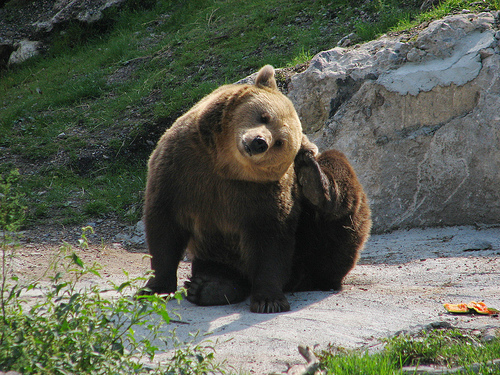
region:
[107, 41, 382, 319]
bear sitting on ground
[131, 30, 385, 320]
the bear is a grizzly bear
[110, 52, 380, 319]
bear is scratching its ear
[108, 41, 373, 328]
the bear is brown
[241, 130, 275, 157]
bear's nose is black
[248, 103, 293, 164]
bear's eyes are black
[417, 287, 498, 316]
orange object on ground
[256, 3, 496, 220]
concrete wall behind bear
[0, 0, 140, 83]
rocks in the grass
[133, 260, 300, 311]
bear's paws on the ground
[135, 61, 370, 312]
large brown colored bear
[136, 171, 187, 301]
large brown colored bear leg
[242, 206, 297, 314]
large brown colored bear leg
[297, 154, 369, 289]
large brown colored bear leg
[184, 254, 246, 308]
large brown colored bear leg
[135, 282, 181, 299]
large brown colored bear paw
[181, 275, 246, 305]
large brown colored bear paw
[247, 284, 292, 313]
large brown colored bear paw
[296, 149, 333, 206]
large brown colored bear paw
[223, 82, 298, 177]
large brown colored bear face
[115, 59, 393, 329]
The bear on the ground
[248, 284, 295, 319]
The paw of the bear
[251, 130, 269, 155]
The nose of the bear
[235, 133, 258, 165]
The mouth of the bear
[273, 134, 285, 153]
The eye of the bear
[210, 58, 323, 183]
The head of the bear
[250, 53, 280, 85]
The ear of the bear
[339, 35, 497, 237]
The boulder is the color grey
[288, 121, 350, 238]
The bear is scratching his ear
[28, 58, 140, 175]
The grass is short and green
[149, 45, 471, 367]
Bear scratching its head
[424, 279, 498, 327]
Fruit has been eaten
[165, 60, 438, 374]
The bear is very fat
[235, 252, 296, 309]
Bear has long claws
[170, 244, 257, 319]
Bear has a padded foot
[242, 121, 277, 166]
Bear has a black nose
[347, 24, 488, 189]
Rocks behind the bear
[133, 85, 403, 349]
The bear is fuzzy and brown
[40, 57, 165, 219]
Grass has dry patches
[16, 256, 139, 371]
Weeds growing beside the rock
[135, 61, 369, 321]
brown bear scratching ear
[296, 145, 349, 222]
back foot of a bear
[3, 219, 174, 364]
green leaves of a shrub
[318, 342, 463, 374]
grass growing in concrete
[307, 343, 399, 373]
clump of green grass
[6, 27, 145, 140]
grass growing on a hill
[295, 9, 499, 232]
large grey rock behind bear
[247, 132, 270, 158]
nose of a bear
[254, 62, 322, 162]
ears of a bear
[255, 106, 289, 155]
eyes of a bear